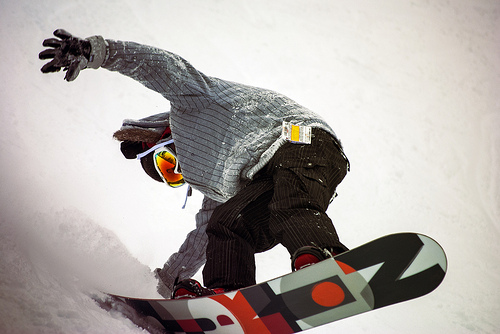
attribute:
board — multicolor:
[110, 248, 440, 327]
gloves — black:
[42, 25, 112, 89]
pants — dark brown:
[205, 133, 353, 283]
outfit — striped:
[85, 33, 348, 294]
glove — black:
[37, 28, 90, 83]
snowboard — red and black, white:
[76, 230, 449, 332]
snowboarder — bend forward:
[36, 26, 350, 298]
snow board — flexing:
[79, 231, 449, 332]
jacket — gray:
[87, 34, 340, 299]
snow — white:
[64, 53, 89, 69]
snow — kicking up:
[55, 208, 159, 294]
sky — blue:
[351, 2, 485, 186]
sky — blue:
[410, 54, 458, 104]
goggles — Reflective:
[152, 144, 184, 189]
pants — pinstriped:
[201, 126, 349, 290]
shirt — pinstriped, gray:
[87, 34, 336, 202]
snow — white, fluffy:
[0, 203, 154, 333]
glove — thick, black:
[38, 26, 89, 79]